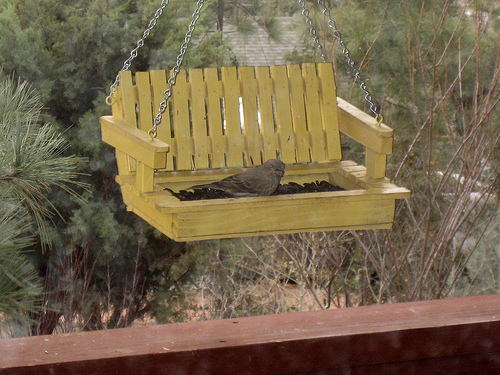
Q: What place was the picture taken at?
A: It was taken at the backyard.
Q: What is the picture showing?
A: It is showing a backyard.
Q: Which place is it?
A: It is a backyard.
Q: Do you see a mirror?
A: No, there are no mirrors.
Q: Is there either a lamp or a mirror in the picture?
A: No, there are no mirrors or lamps.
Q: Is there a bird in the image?
A: Yes, there is a bird.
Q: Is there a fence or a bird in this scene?
A: Yes, there is a bird.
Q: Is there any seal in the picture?
A: No, there are no seals.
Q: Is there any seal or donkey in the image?
A: No, there are no seals or donkeys.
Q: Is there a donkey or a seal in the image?
A: No, there are no seals or donkeys.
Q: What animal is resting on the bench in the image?
A: The bird is resting on the bench.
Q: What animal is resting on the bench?
A: The bird is resting on the bench.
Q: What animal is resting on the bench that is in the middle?
A: The animal is a bird.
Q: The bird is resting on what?
A: The bird is resting on the bench.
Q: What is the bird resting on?
A: The bird is resting on the bench.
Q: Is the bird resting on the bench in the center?
A: Yes, the bird is resting on the bench.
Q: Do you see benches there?
A: Yes, there is a bench.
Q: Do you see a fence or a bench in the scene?
A: Yes, there is a bench.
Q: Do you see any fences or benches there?
A: Yes, there is a bench.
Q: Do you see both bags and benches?
A: No, there is a bench but no bags.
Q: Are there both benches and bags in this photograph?
A: No, there is a bench but no bags.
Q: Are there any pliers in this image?
A: No, there are no pliers.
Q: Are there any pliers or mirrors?
A: No, there are no pliers or mirrors.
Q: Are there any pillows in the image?
A: No, there are no pillows.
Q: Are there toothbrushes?
A: No, there are no toothbrushes.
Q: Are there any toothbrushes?
A: No, there are no toothbrushes.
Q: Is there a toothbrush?
A: No, there are no toothbrushes.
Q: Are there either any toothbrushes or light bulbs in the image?
A: No, there are no toothbrushes or light bulbs.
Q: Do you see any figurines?
A: No, there are no figurines.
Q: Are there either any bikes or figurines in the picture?
A: No, there are no figurines or bikes.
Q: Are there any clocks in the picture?
A: No, there are no clocks.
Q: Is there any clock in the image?
A: No, there are no clocks.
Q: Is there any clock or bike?
A: No, there are no clocks or bikes.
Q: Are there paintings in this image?
A: No, there are no paintings.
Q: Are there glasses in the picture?
A: No, there are no glasses.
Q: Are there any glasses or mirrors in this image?
A: No, there are no glasses or mirrors.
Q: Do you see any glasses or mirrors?
A: No, there are no glasses or mirrors.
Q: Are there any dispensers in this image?
A: No, there are no dispensers.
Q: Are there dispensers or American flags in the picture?
A: No, there are no dispensers or American flags.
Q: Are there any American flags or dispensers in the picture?
A: No, there are no dispensers or American flags.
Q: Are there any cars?
A: No, there are no cars.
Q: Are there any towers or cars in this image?
A: No, there are no cars or towers.